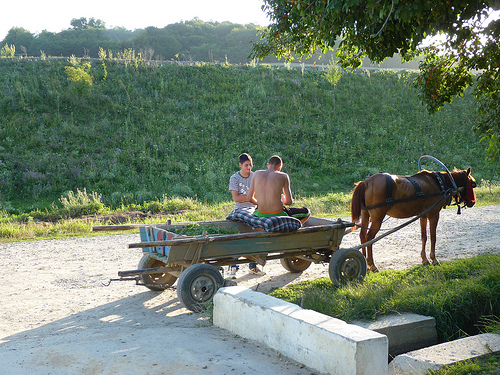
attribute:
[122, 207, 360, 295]
cart — wooden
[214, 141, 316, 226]
men — young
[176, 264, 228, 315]
wheel — black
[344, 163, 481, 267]
horse — brown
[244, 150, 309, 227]
man — young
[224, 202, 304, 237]
pillow — checkered, black, white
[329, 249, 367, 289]
wheel — black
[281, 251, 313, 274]
wheel — black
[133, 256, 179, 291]
wheel — black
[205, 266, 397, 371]
block — white, cement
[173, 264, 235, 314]
wheel — black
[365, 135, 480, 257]
horse — brown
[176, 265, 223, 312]
wheel — black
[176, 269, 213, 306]
wheel — black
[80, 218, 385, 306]
wood wagon — wooden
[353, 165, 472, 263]
horse — hooked up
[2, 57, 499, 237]
grassy hill — steep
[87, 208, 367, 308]
cart — wooden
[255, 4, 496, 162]
leaves — green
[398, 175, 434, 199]
ribs — sticking out